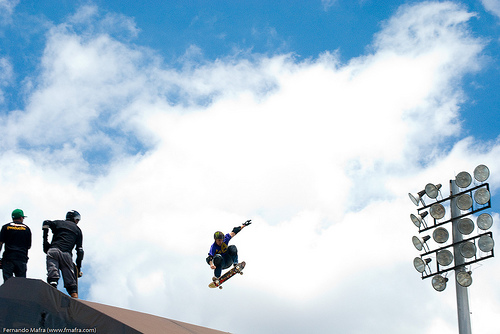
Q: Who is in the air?
A: A skateboarder.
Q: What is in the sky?
A: Clouds.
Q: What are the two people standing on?
A: Skateboards.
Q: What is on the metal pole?
A: Multiple light bulbs.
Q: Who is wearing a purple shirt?
A: Skateboarder in the air.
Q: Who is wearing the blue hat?
A: Man in a black shirt.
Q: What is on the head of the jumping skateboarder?
A: Black helmet.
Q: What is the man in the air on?
A: Skateboard.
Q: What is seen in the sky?
A: White clouds.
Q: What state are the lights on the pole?
A: Powered off.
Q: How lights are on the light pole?
A: 18.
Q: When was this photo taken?
A: During the daytime.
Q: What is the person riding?
A: Skateboard.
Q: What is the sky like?
A: Partly cloudy.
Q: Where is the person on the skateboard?
A: Flying in the air.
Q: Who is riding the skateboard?
A: The person with the helmet.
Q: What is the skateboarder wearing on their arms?
A: Elbow protection.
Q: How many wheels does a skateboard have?
A: 4.